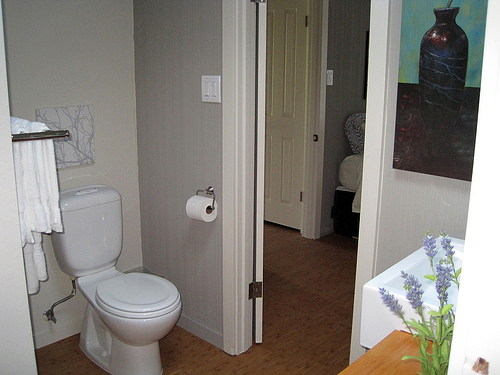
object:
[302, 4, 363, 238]
wall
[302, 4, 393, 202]
bathroom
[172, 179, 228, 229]
holder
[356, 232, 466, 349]
arrangement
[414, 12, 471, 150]
artwork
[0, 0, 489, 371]
bathroom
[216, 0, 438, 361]
doorway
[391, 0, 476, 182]
painting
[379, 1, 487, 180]
vase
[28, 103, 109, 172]
artwork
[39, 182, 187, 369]
stool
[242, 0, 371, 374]
door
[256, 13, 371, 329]
room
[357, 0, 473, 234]
wall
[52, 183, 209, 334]
toilet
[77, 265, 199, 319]
seat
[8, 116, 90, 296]
towels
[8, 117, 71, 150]
rack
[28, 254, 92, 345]
valve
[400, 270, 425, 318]
flowers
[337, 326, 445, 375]
table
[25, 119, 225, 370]
toilet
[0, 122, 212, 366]
bathroom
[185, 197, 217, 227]
paper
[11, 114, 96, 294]
towels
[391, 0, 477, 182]
picture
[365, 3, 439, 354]
wall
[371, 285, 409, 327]
flowers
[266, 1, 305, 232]
door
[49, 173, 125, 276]
tank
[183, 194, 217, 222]
tissue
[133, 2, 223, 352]
wall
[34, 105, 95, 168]
picture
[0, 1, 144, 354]
wall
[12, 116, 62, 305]
towel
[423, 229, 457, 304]
flowers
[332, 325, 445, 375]
table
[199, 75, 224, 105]
light switch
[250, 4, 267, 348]
door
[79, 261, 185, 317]
lid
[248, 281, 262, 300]
hinge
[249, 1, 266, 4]
hinge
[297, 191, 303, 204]
hinge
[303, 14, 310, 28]
hinge